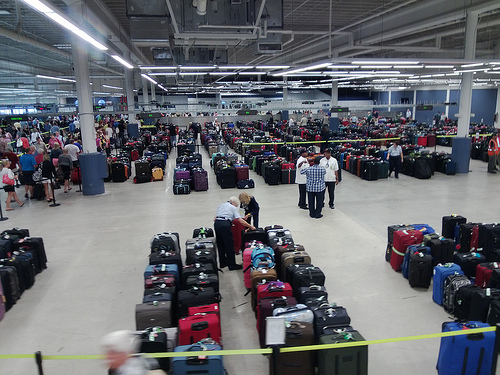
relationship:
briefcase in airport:
[305, 298, 333, 310] [1, 0, 500, 374]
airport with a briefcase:
[1, 0, 500, 374] [305, 298, 333, 310]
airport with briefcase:
[1, 0, 500, 374] [305, 298, 333, 310]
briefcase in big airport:
[305, 298, 333, 310] [1, 0, 500, 374]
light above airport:
[110, 52, 136, 71] [1, 0, 500, 374]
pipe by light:
[164, 6, 266, 48] [110, 52, 136, 71]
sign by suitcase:
[264, 316, 288, 347] [140, 271, 176, 297]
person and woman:
[212, 193, 258, 270] [386, 139, 406, 181]